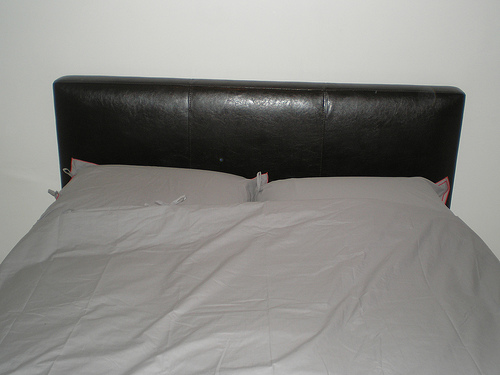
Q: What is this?
A: Bed.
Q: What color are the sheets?
A: White.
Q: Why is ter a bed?
A: Resting.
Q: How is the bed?
A: Empty.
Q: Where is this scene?
A: Bedroom.